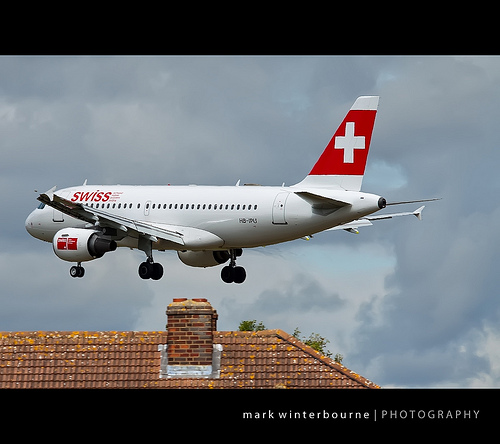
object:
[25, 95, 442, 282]
plane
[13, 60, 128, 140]
air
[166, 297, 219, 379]
chimney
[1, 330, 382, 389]
roof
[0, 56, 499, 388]
clouds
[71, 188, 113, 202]
logo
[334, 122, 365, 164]
cross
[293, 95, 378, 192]
tail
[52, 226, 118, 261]
engine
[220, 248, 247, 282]
gear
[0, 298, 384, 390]
house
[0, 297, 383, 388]
neighborhood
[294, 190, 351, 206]
wing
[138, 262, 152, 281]
wheels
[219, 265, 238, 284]
wheels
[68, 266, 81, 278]
wheels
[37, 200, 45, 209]
windshield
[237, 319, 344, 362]
tree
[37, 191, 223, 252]
wing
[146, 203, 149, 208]
windows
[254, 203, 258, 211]
windows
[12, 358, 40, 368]
tile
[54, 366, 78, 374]
tile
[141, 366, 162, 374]
tile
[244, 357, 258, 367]
tile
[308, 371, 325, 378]
tile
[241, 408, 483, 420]
logo